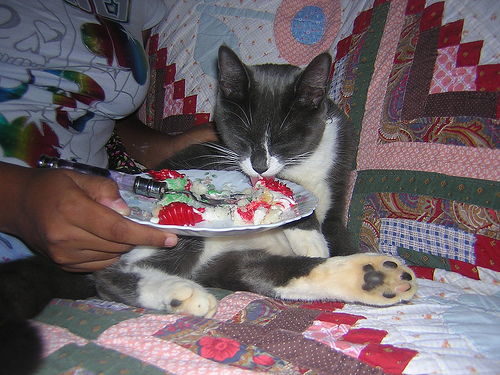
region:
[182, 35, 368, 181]
head of a cat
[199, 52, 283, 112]
ear of a cat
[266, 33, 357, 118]
ear of a cat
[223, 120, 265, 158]
an eye of a cat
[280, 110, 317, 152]
an eye of a cat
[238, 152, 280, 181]
nose of a cat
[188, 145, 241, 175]
whisker of a cat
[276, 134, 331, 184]
whisker of a cat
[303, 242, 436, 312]
leg of a cat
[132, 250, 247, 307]
leg of a cat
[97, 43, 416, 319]
A gray and white cat.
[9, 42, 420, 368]
A gray and white cat eating icing.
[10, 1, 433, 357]
A woman feeding the cat icing.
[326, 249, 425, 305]
Bottom of the cat's paw.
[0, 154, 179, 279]
Right hand of the woman.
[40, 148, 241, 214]
A spoon on the plate.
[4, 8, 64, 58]
Hearts on the woman's shirt.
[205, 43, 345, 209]
Cat licking food off the plate.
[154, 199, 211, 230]
Red icing on the plate.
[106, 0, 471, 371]
A quilted blanket on the couch.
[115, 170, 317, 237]
a plate with cake on it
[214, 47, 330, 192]
cat is eating cake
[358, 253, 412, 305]
the paw of a cat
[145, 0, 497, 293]
pillow on the bed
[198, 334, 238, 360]
the flower is pink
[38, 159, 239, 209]
fork on the plate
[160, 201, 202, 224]
the frosting is red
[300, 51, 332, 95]
ear of a cat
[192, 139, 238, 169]
the whiskers are white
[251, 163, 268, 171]
nose of a cat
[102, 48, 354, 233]
Grey and white cat eating birthday cake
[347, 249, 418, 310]
Grey and pink cat's paw pads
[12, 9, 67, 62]
Two grey and white hearts on woman's shirt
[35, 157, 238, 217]
Steel and plastic fork on plate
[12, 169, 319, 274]
Woman holding white plate with pink flowers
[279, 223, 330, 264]
White mitten on cat's front paw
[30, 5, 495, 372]
Pink, green, red, blue and white quilt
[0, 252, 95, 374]
Grey tail belonging to a cat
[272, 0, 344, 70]
Circular shapes on bedspread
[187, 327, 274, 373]
Rose shapes on bedspread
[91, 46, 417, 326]
Cat sitting on couch eating from plate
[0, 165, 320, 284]
Hand holding plate of food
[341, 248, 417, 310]
Cat's paw on the quilt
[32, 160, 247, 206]
Fork on the plate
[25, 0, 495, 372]
Quilt on the sofa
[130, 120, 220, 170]
Person's hand on the cat's back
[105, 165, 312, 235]
Lobster pieces on a plate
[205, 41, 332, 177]
Black and white face of a cat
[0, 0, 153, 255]
Woman's print shirt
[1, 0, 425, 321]
Cat and person on the couch